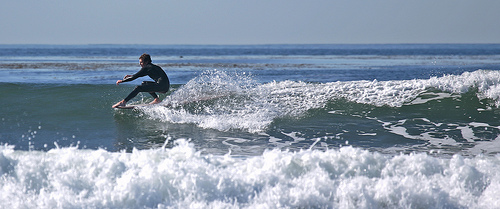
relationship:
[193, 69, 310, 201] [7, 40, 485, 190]
saltwater all across ocean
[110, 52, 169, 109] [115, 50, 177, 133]
surfer wearing wetsuit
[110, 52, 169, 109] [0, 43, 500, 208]
surfer in saltwater